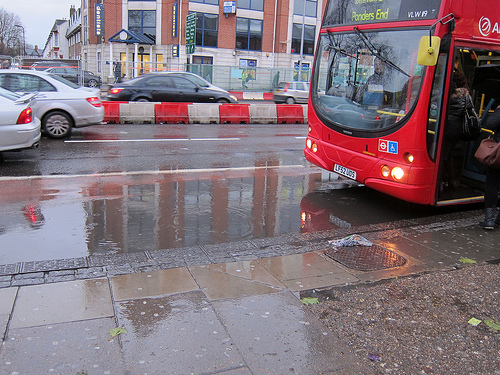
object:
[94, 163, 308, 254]
cement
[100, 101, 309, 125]
barricade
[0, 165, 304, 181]
line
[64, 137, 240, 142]
line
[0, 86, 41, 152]
car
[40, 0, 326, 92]
building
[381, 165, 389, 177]
headlight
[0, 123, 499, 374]
ground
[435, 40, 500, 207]
door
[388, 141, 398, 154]
handicap sticker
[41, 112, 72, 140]
wheel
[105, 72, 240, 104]
car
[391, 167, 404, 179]
headlight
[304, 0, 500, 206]
bus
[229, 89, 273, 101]
barrier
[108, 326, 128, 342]
leaf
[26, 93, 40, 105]
zipper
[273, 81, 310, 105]
vehicles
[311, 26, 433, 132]
windshield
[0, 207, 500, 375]
sidewalk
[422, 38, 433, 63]
yellow back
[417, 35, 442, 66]
mirror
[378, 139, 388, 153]
sign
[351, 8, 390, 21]
sign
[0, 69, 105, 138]
car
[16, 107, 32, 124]
tail light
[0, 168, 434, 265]
puddle